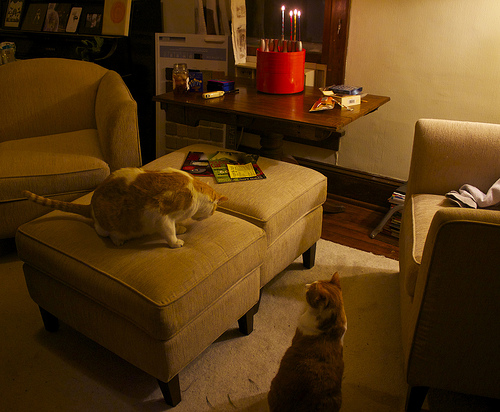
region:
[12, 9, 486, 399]
The cats are in somebody's house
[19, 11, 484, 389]
The cats are in a room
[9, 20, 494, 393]
The cats belong to somebody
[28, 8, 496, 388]
The cats are looking for their master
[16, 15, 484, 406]
The cats are getting along together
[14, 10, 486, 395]
The cats are male and female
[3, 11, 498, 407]
The cats are wanting to play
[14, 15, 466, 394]
The cats are waiting to be fed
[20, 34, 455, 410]
The cats are cleaning themselves nicely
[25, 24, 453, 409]
The cats are enjoying the evening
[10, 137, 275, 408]
cat sitting on an ottoman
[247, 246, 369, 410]
cat sitting on the floor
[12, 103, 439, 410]
two cats in the living room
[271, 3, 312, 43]
tall, lit candles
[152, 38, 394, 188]
dark brown table against the wal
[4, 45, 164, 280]
tan armchair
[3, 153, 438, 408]
cream colored rug on the floor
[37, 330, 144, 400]
shadow from the ottoman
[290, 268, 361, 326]
head turned to the side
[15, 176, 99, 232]
striped tail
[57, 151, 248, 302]
cat on an ottoman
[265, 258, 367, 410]
the cat is looking up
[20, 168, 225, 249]
an orange and white cat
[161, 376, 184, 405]
the leg of the chair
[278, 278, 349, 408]
a brown and white cat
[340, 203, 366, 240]
the hardwood floor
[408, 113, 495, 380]
a chair on the side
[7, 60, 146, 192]
a large white chair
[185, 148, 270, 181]
magazine on the chair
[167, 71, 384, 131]
a small table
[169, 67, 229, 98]
items on the table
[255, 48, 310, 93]
a red cup on the table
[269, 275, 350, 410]
a cat standing on the floor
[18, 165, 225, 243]
a cat sitting on a chair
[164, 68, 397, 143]
a wood desk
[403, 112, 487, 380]
a white chair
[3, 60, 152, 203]
an arm chair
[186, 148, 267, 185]
magazines on the chair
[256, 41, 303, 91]
a red bucket on the table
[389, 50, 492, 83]
a white wall in the background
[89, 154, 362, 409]
two cats